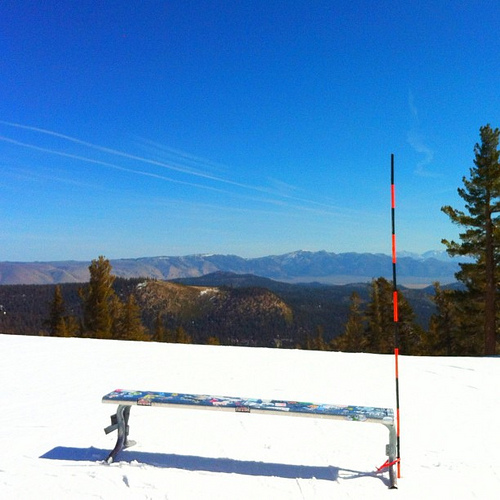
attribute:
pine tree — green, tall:
[431, 117, 499, 359]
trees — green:
[262, 267, 408, 307]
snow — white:
[2, 335, 495, 497]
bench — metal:
[94, 373, 399, 498]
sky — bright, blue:
[173, 55, 395, 151]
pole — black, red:
[384, 153, 407, 499]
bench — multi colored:
[97, 381, 402, 493]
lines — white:
[63, 110, 315, 217]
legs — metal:
[94, 391, 158, 455]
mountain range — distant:
[1, 247, 498, 301]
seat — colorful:
[109, 381, 399, 433]